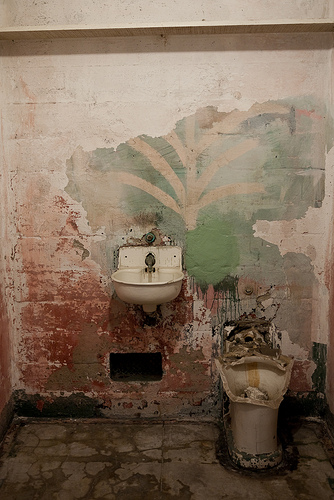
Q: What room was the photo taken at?
A: It was taken at the bathroom.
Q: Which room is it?
A: It is a bathroom.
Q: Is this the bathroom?
A: Yes, it is the bathroom.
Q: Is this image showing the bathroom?
A: Yes, it is showing the bathroom.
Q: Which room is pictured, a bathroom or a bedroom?
A: It is a bathroom.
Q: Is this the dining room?
A: No, it is the bathroom.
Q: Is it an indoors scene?
A: Yes, it is indoors.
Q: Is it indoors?
A: Yes, it is indoors.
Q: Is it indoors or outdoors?
A: It is indoors.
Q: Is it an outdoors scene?
A: No, it is indoors.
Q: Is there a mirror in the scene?
A: No, there are no mirrors.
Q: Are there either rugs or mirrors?
A: No, there are no mirrors or rugs.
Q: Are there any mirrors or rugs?
A: No, there are no mirrors or rugs.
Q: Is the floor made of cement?
A: Yes, the floor is made of cement.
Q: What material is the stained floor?
A: The floor is made of concrete.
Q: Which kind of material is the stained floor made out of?
A: The floor is made of concrete.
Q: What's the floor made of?
A: The floor is made of concrete.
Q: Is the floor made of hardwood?
A: No, the floor is made of concrete.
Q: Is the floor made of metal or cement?
A: The floor is made of cement.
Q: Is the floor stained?
A: Yes, the floor is stained.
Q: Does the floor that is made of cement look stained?
A: Yes, the floor is stained.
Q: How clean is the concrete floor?
A: The floor is stained.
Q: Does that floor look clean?
A: No, the floor is stained.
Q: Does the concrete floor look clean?
A: No, the floor is stained.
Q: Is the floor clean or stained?
A: The floor is stained.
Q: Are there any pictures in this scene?
A: No, there are no pictures.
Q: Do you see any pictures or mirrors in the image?
A: No, there are no pictures or mirrors.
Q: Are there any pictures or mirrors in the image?
A: No, there are no pictures or mirrors.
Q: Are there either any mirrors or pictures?
A: No, there are no pictures or mirrors.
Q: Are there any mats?
A: No, there are no mats.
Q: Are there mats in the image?
A: No, there are no mats.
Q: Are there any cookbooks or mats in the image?
A: No, there are no mats or cookbooks.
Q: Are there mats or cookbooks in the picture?
A: No, there are no mats or cookbooks.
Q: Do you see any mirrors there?
A: No, there are no mirrors.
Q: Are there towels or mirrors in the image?
A: No, there are no mirrors or towels.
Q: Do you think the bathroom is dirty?
A: Yes, the bathroom is dirty.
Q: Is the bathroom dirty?
A: Yes, the bathroom is dirty.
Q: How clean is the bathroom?
A: The bathroom is dirty.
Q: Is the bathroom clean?
A: No, the bathroom is dirty.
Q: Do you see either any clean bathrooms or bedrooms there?
A: No, there is a bathroom but it is dirty.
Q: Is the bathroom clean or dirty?
A: The bathroom is dirty.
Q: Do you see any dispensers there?
A: No, there are no dispensers.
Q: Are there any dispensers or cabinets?
A: No, there are no dispensers or cabinets.